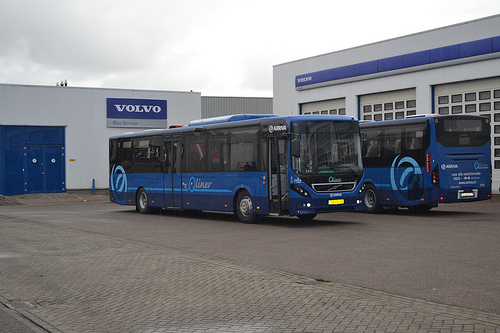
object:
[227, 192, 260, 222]
tire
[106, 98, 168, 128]
sign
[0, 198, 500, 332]
road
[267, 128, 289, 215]
entry door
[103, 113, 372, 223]
bus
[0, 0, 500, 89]
clouds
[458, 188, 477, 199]
plate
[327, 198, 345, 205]
plate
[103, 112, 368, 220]
wave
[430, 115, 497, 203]
door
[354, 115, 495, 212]
bus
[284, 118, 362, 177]
windshield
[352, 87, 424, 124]
garage door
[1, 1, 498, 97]
sky